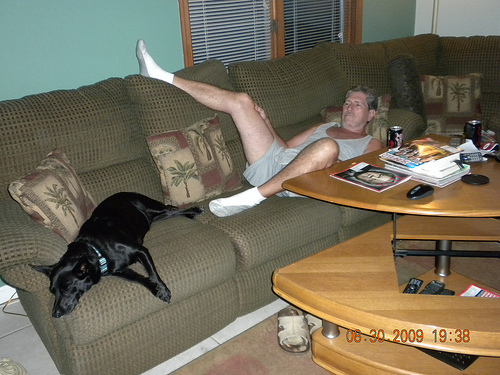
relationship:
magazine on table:
[332, 161, 411, 193] [281, 130, 498, 217]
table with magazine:
[270, 132, 497, 373] [326, 160, 413, 192]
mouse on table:
[405, 182, 433, 199] [281, 130, 498, 217]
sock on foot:
[209, 186, 266, 217] [128, 30, 188, 96]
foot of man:
[134, 39, 275, 165] [126, 35, 383, 217]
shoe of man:
[273, 301, 313, 353] [126, 35, 383, 217]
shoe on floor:
[273, 301, 313, 353] [0, 293, 330, 373]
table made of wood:
[270, 132, 497, 373] [276, 271, 416, 290]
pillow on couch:
[8, 147, 98, 243] [2, 32, 498, 370]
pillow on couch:
[145, 113, 245, 205] [2, 32, 498, 370]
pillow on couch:
[416, 70, 486, 133] [2, 32, 498, 370]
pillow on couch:
[322, 94, 394, 147] [2, 32, 498, 370]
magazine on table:
[329, 161, 413, 193] [270, 132, 497, 373]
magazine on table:
[377, 136, 465, 169] [270, 132, 497, 373]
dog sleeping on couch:
[30, 190, 205, 316] [2, 32, 498, 370]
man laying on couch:
[126, 35, 383, 217] [2, 32, 498, 370]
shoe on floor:
[274, 307, 310, 354] [5, 300, 339, 372]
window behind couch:
[178, 1, 363, 65] [2, 32, 498, 370]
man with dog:
[126, 35, 383, 217] [30, 190, 205, 316]